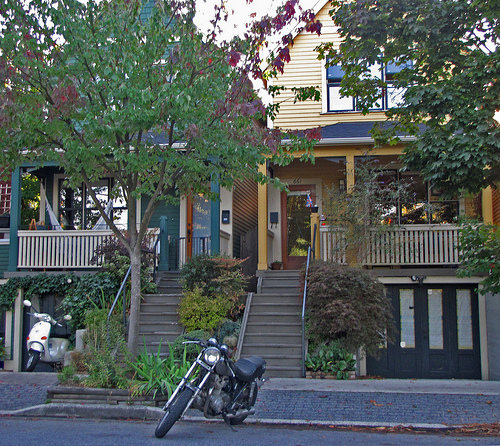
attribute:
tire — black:
[150, 383, 198, 438]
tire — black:
[23, 348, 38, 373]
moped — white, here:
[20, 299, 73, 376]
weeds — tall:
[82, 351, 122, 388]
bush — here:
[310, 257, 377, 351]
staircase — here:
[235, 263, 312, 378]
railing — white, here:
[16, 226, 129, 273]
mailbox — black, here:
[267, 204, 283, 230]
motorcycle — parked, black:
[150, 339, 268, 435]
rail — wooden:
[319, 225, 488, 268]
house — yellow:
[252, 2, 498, 276]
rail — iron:
[104, 262, 132, 346]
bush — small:
[181, 295, 224, 330]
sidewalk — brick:
[257, 385, 489, 427]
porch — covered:
[25, 156, 172, 273]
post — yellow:
[253, 154, 272, 271]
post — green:
[203, 151, 229, 270]